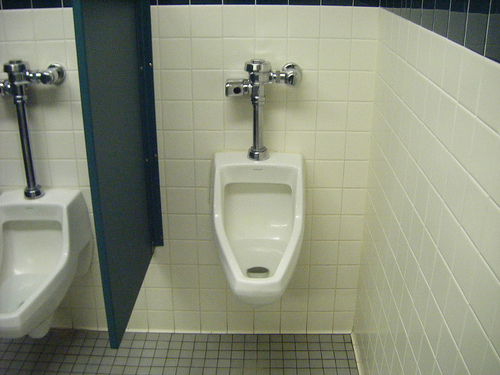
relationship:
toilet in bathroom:
[213, 149, 307, 307] [16, 16, 473, 363]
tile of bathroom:
[157, 12, 374, 52] [16, 16, 473, 363]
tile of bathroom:
[425, 6, 499, 47] [16, 16, 473, 363]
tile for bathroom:
[13, 326, 352, 374] [16, 16, 473, 363]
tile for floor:
[13, 326, 352, 374] [24, 335, 349, 374]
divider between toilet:
[69, 15, 160, 291] [213, 149, 307, 307]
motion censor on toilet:
[233, 86, 242, 95] [213, 149, 307, 307]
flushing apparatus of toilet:
[228, 78, 271, 96] [213, 149, 307, 307]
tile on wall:
[157, 12, 374, 52] [147, 8, 364, 121]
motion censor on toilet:
[233, 77, 243, 98] [213, 149, 307, 307]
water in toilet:
[247, 256, 276, 284] [213, 149, 307, 307]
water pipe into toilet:
[253, 105, 265, 148] [213, 149, 307, 307]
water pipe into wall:
[253, 105, 265, 148] [147, 8, 364, 121]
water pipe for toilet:
[8, 110, 43, 182] [0, 188, 96, 340]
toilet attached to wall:
[213, 149, 307, 307] [147, 8, 364, 121]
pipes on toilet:
[250, 95, 269, 158] [213, 149, 307, 307]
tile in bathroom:
[157, 12, 374, 52] [16, 16, 473, 363]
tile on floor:
[13, 326, 352, 374] [24, 335, 349, 374]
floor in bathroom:
[24, 335, 349, 374] [16, 16, 473, 363]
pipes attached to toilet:
[250, 95, 269, 158] [213, 149, 307, 307]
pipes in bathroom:
[250, 95, 269, 158] [16, 16, 473, 363]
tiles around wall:
[401, 0, 499, 48] [147, 8, 364, 121]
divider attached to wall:
[69, 15, 160, 291] [147, 8, 364, 121]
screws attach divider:
[146, 62, 156, 71] [69, 15, 160, 291]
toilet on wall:
[217, 143, 307, 283] [147, 8, 364, 121]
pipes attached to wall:
[250, 95, 269, 158] [147, 8, 364, 121]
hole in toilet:
[249, 266, 270, 282] [217, 143, 307, 283]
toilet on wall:
[0, 201, 86, 343] [147, 8, 364, 121]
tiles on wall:
[401, 0, 499, 48] [147, 8, 364, 121]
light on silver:
[255, 109, 263, 121] [253, 63, 266, 162]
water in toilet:
[247, 256, 276, 284] [217, 143, 307, 283]